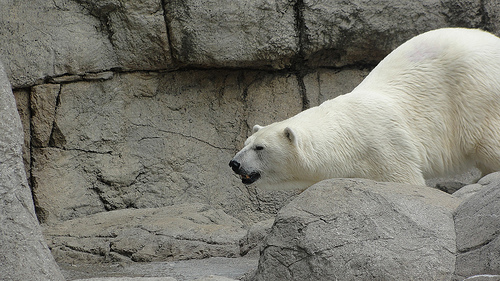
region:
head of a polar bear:
[212, 108, 297, 195]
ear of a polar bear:
[270, 113, 304, 157]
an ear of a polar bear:
[275, 123, 297, 160]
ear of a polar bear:
[251, 109, 263, 133]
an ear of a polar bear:
[248, 116, 262, 144]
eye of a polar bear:
[254, 143, 279, 155]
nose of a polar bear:
[222, 149, 246, 171]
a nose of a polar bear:
[225, 159, 249, 170]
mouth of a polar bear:
[232, 166, 262, 196]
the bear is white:
[190, 39, 497, 214]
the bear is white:
[182, 42, 479, 227]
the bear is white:
[182, 47, 494, 232]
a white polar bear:
[177, 37, 496, 245]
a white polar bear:
[213, 67, 488, 227]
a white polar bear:
[181, 27, 497, 222]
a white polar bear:
[203, 74, 478, 221]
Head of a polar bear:
[224, 118, 303, 195]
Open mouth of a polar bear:
[226, 148, 265, 192]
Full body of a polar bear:
[202, 31, 498, 187]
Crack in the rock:
[30, 75, 66, 141]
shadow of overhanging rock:
[121, 55, 313, 82]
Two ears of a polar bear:
[239, 113, 304, 143]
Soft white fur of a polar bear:
[378, 102, 475, 147]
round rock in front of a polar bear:
[262, 166, 457, 279]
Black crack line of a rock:
[290, 3, 308, 52]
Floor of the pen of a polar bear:
[74, 250, 237, 279]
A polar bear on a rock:
[215, 23, 496, 215]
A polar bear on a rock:
[219, 19, 495, 219]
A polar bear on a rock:
[219, 19, 491, 234]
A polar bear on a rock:
[209, 19, 499, 219]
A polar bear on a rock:
[216, 19, 488, 209]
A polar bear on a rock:
[206, 21, 494, 204]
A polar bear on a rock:
[221, 24, 490, 206]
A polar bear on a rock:
[221, 19, 491, 213]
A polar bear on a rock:
[221, 17, 493, 203]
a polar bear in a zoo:
[203, 12, 497, 212]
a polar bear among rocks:
[197, 23, 499, 279]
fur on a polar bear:
[395, 55, 499, 137]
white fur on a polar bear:
[377, 84, 489, 137]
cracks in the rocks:
[19, 96, 94, 175]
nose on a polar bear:
[226, 158, 244, 170]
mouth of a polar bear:
[235, 168, 259, 185]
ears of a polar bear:
[250, 117, 302, 141]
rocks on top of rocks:
[12, 7, 375, 114]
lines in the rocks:
[137, 6, 406, 110]